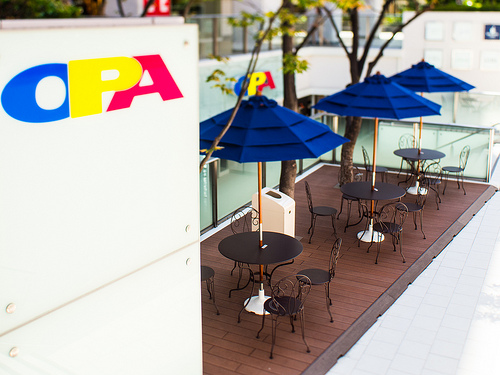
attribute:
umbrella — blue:
[310, 69, 441, 119]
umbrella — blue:
[199, 93, 353, 249]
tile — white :
[388, 277, 480, 352]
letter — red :
[104, 51, 183, 114]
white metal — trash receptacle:
[248, 183, 300, 241]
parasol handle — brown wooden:
[257, 162, 264, 250]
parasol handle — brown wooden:
[371, 116, 376, 185]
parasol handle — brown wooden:
[419, 92, 423, 151]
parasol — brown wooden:
[202, 93, 348, 165]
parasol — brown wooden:
[309, 69, 439, 116]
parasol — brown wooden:
[388, 58, 480, 92]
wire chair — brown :
[272, 160, 412, 278]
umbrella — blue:
[197, 89, 347, 162]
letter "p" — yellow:
[67, 54, 142, 116]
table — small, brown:
[214, 217, 301, 289]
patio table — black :
[303, 154, 435, 281]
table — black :
[206, 199, 298, 267]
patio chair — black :
[228, 262, 333, 365]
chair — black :
[306, 242, 351, 322]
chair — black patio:
[253, 267, 317, 361]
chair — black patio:
[287, 228, 351, 329]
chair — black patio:
[220, 198, 273, 283]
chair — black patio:
[292, 170, 349, 253]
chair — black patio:
[359, 193, 415, 274]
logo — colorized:
[9, 48, 225, 156]